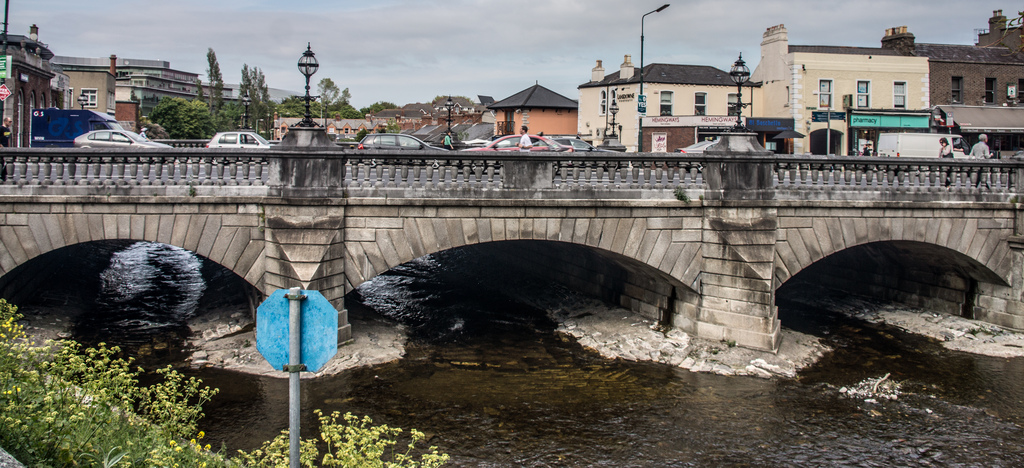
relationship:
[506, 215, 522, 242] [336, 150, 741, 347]
stone in wall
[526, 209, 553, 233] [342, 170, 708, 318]
stone in wall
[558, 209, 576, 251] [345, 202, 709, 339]
stone in wall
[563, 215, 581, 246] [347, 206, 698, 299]
stone in wall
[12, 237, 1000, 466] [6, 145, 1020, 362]
water under bridge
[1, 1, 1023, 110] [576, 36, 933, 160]
sky above building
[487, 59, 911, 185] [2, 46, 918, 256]
building in city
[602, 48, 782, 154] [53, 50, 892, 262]
building in city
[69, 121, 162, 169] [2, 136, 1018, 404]
car on bridge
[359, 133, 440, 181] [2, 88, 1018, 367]
car on bridge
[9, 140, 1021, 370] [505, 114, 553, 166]
person walking on bridge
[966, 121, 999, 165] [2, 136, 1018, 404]
person walking on bridge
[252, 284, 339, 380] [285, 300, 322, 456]
road sign on pole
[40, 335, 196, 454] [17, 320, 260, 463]
yellow flowers on bush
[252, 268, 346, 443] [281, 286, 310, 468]
road sign on pole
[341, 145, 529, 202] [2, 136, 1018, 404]
wooden poles protecting bridge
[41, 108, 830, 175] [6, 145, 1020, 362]
vehicles travelling on top of bridge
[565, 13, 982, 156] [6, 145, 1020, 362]
buildings beside bridge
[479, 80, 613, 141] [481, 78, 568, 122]
building with grey roof